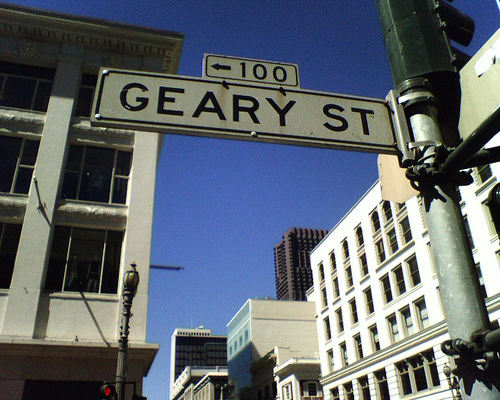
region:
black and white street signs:
[85, 46, 392, 162]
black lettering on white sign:
[118, 73, 374, 133]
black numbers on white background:
[233, 54, 289, 86]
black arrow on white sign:
[207, 57, 238, 77]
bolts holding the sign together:
[92, 65, 289, 147]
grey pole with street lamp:
[118, 253, 145, 398]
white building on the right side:
[297, 148, 491, 398]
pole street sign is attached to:
[405, 95, 493, 389]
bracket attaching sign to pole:
[385, 88, 431, 165]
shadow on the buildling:
[42, 245, 110, 336]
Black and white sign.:
[86, 52, 398, 155]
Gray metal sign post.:
[378, 0, 498, 399]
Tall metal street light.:
[111, 258, 141, 398]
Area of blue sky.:
[138, 131, 378, 398]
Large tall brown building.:
[272, 227, 333, 302]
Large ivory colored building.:
[226, 298, 321, 396]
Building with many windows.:
[311, 176, 461, 398]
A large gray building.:
[1, 3, 189, 398]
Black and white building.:
[170, 324, 228, 389]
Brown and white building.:
[273, 355, 325, 399]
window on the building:
[417, 298, 432, 328]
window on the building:
[399, 305, 419, 336]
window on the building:
[385, 312, 404, 344]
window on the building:
[366, 324, 381, 350]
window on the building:
[353, 335, 370, 360]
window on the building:
[340, 342, 352, 369]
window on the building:
[328, 350, 335, 370]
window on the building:
[333, 307, 344, 333]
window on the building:
[321, 318, 336, 337]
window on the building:
[327, 274, 345, 294]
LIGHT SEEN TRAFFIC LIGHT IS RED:
[89, 379, 139, 398]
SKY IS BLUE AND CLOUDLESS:
[150, 2, 423, 236]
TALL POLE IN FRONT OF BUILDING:
[101, 264, 151, 397]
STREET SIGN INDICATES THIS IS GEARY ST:
[83, 51, 421, 168]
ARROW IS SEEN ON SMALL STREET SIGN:
[203, 51, 311, 92]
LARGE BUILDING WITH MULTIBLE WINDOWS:
[314, 171, 499, 397]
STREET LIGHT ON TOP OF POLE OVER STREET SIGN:
[361, 2, 479, 83]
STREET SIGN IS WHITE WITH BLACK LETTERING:
[85, 36, 399, 165]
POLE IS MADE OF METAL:
[382, 87, 492, 373]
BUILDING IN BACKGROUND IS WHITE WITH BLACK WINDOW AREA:
[160, 316, 237, 397]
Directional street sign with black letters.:
[89, 65, 396, 156]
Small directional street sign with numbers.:
[200, 52, 305, 89]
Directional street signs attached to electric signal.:
[89, 1, 498, 398]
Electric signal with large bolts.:
[378, 0, 499, 397]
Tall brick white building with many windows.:
[306, 145, 498, 398]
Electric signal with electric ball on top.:
[99, 256, 154, 398]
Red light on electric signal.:
[96, 257, 147, 397]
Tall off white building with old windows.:
[3, 2, 187, 399]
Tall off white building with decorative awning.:
[1, 2, 186, 399]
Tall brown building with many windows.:
[272, 220, 334, 305]